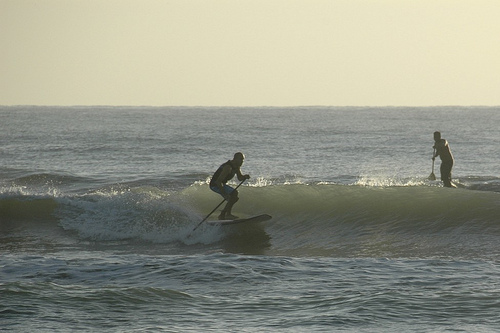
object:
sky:
[0, 0, 500, 107]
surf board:
[201, 213, 274, 226]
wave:
[176, 172, 452, 219]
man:
[427, 129, 454, 189]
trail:
[56, 185, 229, 246]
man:
[208, 149, 252, 221]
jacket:
[208, 159, 243, 184]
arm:
[216, 165, 231, 189]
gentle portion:
[0, 105, 500, 176]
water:
[0, 107, 498, 330]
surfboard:
[443, 182, 456, 188]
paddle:
[428, 146, 438, 181]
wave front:
[177, 187, 500, 253]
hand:
[243, 174, 250, 179]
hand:
[226, 194, 231, 199]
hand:
[431, 156, 437, 161]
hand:
[431, 145, 437, 149]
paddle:
[185, 174, 250, 241]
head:
[231, 150, 246, 166]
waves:
[0, 176, 69, 219]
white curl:
[356, 169, 413, 189]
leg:
[226, 184, 240, 212]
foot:
[224, 213, 240, 221]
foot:
[218, 213, 231, 221]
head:
[432, 130, 442, 142]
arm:
[437, 140, 452, 149]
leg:
[214, 186, 240, 213]